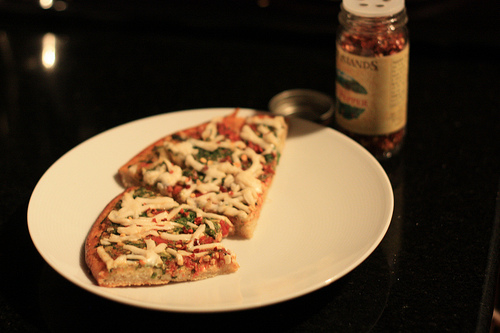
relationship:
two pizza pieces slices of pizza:
[80, 106, 293, 288] [81, 193, 244, 301]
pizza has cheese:
[68, 101, 309, 291] [116, 199, 146, 224]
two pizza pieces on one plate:
[80, 106, 293, 288] [22, 101, 396, 309]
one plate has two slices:
[22, 101, 396, 309] [68, 101, 309, 291]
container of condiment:
[331, 0, 442, 157] [347, 33, 394, 50]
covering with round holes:
[342, 1, 405, 19] [352, 0, 391, 12]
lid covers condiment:
[269, 81, 336, 119] [331, 0, 442, 157]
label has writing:
[326, 47, 422, 132] [336, 53, 378, 125]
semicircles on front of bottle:
[330, 68, 373, 121] [332, 71, 369, 125]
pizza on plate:
[68, 101, 309, 291] [22, 101, 396, 309]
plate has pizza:
[22, 101, 396, 309] [68, 101, 309, 291]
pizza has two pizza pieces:
[68, 101, 309, 291] [80, 106, 293, 288]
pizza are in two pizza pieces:
[68, 101, 309, 291] [80, 106, 293, 288]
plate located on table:
[22, 101, 396, 309] [6, 5, 264, 99]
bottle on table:
[330, 1, 414, 161] [6, 5, 264, 99]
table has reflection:
[6, 5, 264, 99] [28, 0, 79, 78]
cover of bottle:
[342, 1, 414, 19] [330, 1, 414, 161]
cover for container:
[342, 1, 414, 19] [330, 1, 414, 161]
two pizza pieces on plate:
[80, 106, 293, 288] [22, 101, 396, 309]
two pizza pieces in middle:
[80, 106, 293, 288] [83, 106, 311, 308]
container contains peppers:
[331, 0, 409, 157] [347, 38, 400, 51]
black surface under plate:
[64, 10, 304, 82] [22, 101, 396, 309]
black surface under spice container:
[64, 10, 304, 82] [334, 16, 418, 160]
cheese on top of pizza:
[116, 199, 146, 224] [81, 193, 244, 301]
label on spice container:
[326, 47, 422, 132] [334, 16, 418, 160]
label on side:
[384, 51, 414, 129] [384, 52, 412, 129]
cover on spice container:
[342, 1, 414, 19] [334, 16, 418, 160]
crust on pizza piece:
[82, 204, 99, 281] [81, 185, 233, 284]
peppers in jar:
[347, 38, 400, 51] [330, 1, 414, 161]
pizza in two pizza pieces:
[68, 101, 309, 291] [80, 106, 293, 288]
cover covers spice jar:
[266, 89, 336, 117] [332, 0, 415, 152]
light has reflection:
[35, 1, 67, 74] [28, 0, 79, 78]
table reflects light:
[6, 5, 264, 99] [35, 1, 67, 74]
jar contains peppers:
[335, 11, 412, 53] [347, 38, 400, 51]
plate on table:
[22, 101, 396, 309] [6, 5, 264, 99]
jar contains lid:
[335, 11, 412, 53] [269, 81, 336, 119]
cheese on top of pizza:
[95, 199, 218, 274] [83, 183, 242, 287]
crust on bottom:
[82, 204, 99, 281] [78, 235, 93, 282]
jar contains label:
[335, 11, 412, 53] [326, 47, 422, 132]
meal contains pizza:
[21, 0, 458, 319] [68, 101, 309, 291]